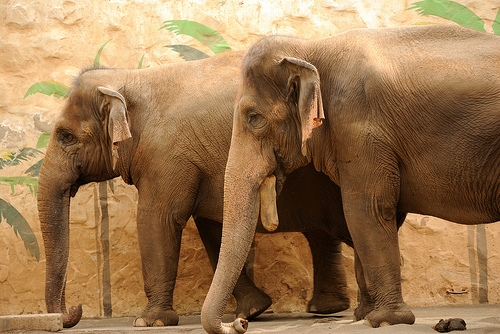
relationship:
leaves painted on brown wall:
[156, 11, 235, 56] [0, 0, 74, 72]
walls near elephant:
[0, 0, 498, 316] [204, 26, 499, 331]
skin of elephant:
[381, 94, 443, 142] [225, 43, 495, 330]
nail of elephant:
[135, 319, 147, 326] [204, 26, 499, 331]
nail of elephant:
[154, 317, 166, 326] [204, 26, 499, 331]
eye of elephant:
[242, 109, 267, 130] [204, 26, 499, 331]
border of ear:
[278, 52, 324, 121] [278, 55, 328, 155]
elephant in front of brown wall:
[36, 51, 408, 327] [0, 0, 74, 72]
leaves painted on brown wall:
[0, 0, 498, 258] [0, 0, 74, 72]